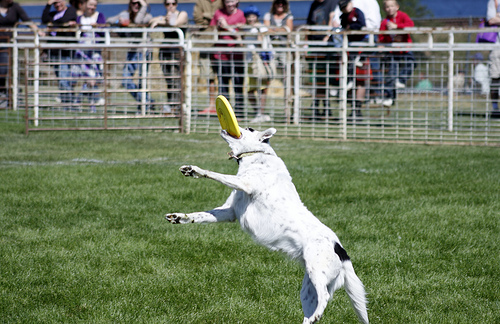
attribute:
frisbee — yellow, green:
[213, 92, 241, 138]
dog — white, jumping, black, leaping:
[165, 126, 371, 323]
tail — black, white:
[331, 234, 377, 324]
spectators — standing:
[1, 0, 497, 120]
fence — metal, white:
[0, 28, 498, 133]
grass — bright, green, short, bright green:
[3, 143, 498, 321]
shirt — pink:
[209, 11, 245, 60]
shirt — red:
[376, 10, 413, 54]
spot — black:
[332, 240, 351, 266]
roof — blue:
[1, 0, 487, 27]